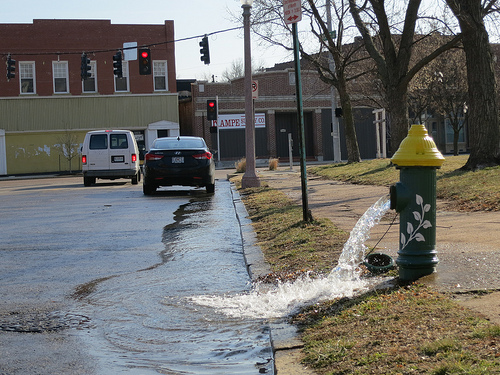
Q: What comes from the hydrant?
A: Water.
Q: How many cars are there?
A: Two.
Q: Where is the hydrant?
A: On the sidewalk.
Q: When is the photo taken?
A: Daytime.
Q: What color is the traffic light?
A: Red.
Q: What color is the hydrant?
A: Yellow, green and white.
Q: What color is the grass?
A: Green.